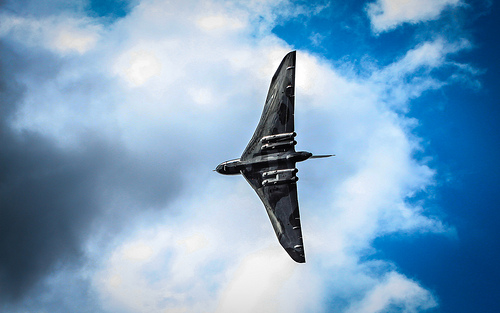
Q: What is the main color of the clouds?
A: White.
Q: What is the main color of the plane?
A: Gray.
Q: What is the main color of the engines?
A: Gray.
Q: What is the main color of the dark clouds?
A: Gray.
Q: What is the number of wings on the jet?
A: Two.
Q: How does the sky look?
A: Cloudy.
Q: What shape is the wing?
A: A triangle.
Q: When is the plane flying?
A: In daylight.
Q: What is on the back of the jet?
A: A tail.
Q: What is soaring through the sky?
A: A jet.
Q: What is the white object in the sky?
A: A cloud.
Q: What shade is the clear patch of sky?
A: Blue.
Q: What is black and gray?
A: The plane.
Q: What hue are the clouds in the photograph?
A: White and grey.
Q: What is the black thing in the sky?
A: Plane.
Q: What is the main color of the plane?
A: Black.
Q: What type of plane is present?
A: Fighter jet.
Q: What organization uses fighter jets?
A: Military.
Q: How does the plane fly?
A: Engines.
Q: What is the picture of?
A: Fighter jet.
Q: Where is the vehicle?
A: In the sky.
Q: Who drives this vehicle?
A: Pilot.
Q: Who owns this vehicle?
A: Military.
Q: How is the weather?
A: Partly cloudy.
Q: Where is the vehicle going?
A: To the base.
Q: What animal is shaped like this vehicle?
A: A hawk.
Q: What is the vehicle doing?
A: Flying.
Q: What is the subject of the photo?
A: A plane.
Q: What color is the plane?
A: Gray.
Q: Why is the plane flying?
A: To travel.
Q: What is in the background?
A: Clouds and blue sky.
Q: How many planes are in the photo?
A: One.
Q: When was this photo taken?
A: During the daytime.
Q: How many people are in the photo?
A: None.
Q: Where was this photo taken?
A: In the sky.